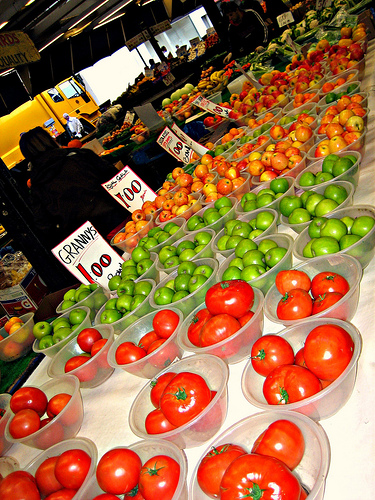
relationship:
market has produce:
[1, 1, 374, 498] [16, 0, 365, 484]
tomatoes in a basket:
[250, 327, 353, 407] [240, 320, 361, 416]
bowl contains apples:
[279, 181, 352, 233] [279, 182, 352, 223]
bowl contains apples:
[308, 133, 366, 165] [313, 116, 363, 155]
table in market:
[8, 40, 375, 494] [1, 1, 374, 498]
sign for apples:
[154, 125, 197, 169] [115, 22, 367, 250]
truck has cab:
[0, 69, 102, 170] [41, 77, 101, 131]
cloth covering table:
[0, 32, 369, 488] [8, 40, 375, 494]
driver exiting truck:
[61, 111, 86, 140] [0, 69, 102, 170]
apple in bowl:
[153, 286, 177, 306] [144, 257, 221, 312]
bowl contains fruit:
[25, 308, 93, 359] [31, 308, 87, 347]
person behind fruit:
[218, 1, 274, 61] [13, 26, 375, 496]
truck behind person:
[0, 69, 102, 170] [92, 102, 128, 135]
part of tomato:
[246, 483, 262, 498] [218, 455, 298, 500]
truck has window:
[0, 69, 102, 170] [57, 80, 84, 102]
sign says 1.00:
[51, 218, 125, 294] [70, 253, 115, 284]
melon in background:
[161, 83, 193, 106] [30, 9, 368, 104]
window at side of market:
[79, 5, 221, 117] [1, 1, 374, 498]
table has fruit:
[8, 40, 375, 494] [4, 270, 355, 500]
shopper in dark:
[18, 127, 128, 256] [8, 85, 218, 324]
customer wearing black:
[18, 127, 128, 256] [31, 149, 129, 240]